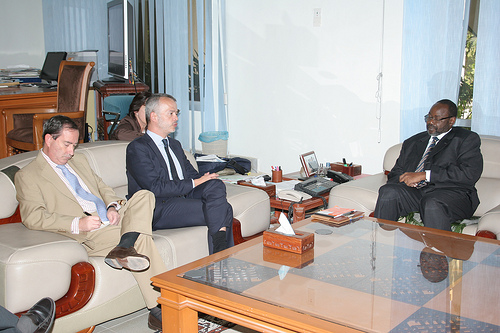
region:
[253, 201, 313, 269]
a box of tissues on a table.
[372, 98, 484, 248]
a man in a black suit sitting.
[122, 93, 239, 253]
a man sitting on a couch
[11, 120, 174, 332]
a man wearing a brown jacket.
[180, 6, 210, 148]
a section of blue mini blinds.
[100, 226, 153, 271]
a shoe on a man's foot.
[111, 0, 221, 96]
a window with blinds over it.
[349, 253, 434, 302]
a section of a table top.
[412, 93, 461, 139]
a human head.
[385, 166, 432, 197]
human hands.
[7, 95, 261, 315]
Two men sitting on the couch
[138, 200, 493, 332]
a large square coffee table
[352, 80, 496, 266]
a man in a suit sitting in a chair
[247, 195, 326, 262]
a brown box of kleenex on the coffee table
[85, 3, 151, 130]
a flat screen tv on a wood stand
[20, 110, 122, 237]
a man wearing a blue tie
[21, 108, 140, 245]
a man writing on a notebook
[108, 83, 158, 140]
a lady sitting behind a man on the couch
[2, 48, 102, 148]
an office desk with two chairs around it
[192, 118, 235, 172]
a small trash can with a blue garbage bag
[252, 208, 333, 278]
tissue box sitting on coffee table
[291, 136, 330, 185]
picture in frame sitting on side tbale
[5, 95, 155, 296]
man in beige suit sitting on couch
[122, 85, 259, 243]
man in gray suit sitting on couch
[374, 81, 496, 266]
man in black suit sitting on couch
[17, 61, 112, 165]
wooden hard back chair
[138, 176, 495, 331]
large coffee table in middle of floor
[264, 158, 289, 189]
brown pencil cup on table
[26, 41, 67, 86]
balck laptop computer sitting on desk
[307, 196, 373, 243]
notepad and planner sitting on table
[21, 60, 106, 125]
a wooden chair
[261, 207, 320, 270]
an orange box of tissue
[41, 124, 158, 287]
man crossing his leg with his knee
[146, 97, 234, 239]
man wearing a blue suit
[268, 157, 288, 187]
a bunch of pens in a brown pot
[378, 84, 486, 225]
man wearing black suit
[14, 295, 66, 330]
tip of a leather shoe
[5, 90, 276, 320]
two men sitting on a couch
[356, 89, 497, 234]
man sitting in an armchair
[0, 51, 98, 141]
wood table with two chairs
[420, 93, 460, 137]
the head of a man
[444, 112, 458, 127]
the ear of a man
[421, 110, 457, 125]
a pair of glasses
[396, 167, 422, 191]
the hand of a man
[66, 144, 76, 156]
the nose of a man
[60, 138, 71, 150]
the eye of a man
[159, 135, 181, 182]
a black neck tie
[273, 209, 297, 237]
a white tissue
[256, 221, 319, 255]
a box of tissue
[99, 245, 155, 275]
a brown shoe on the man